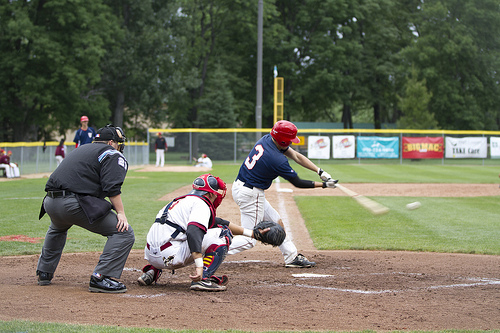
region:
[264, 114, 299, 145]
red helmet on player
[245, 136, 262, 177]
3 on back of the jersey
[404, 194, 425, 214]
baseball in the air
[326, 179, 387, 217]
bat in the hitter's hand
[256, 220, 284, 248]
black glove on catcher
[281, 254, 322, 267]
black shoe on right foot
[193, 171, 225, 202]
catcher's mask on face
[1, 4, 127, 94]
trees behind the fence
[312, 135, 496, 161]
advertisements on the fence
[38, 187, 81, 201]
belt on the umpire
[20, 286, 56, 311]
Small indentons in the dirt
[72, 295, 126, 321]
Small indentons in the dirt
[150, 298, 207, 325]
Small indentons in the dirt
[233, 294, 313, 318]
Small indentons in the dirt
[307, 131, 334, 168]
Banner hanging on fence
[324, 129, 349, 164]
Banner hanging on fence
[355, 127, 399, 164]
Banner hanging on fence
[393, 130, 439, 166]
Banner hanging on fence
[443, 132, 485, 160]
Banner hanging on fence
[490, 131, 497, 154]
Banner hanging on fence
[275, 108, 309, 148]
Person wearing red helmet.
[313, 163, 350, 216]
Person wearing white gloves.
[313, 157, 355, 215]
Person swinging baseball bat.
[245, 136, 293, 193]
Person wearing blue shirt.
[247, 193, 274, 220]
Person wearing white pants.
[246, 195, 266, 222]
Red stripe down pant leg.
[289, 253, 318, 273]
Person wearing black tennis shoes.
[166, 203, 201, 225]
Person wearing white shirt.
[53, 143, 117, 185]
Man wearing black shirt.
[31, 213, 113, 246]
Man wearing gray pants.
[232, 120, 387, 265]
A man wearing a blue jersey swinging a baseball bat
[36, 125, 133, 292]
An umpire in all black clothing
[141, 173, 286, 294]
A catcher squatting down and holding a catchers mitt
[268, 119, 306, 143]
Hard red baseball helmet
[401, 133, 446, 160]
Large red poster hanging on a fence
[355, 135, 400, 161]
Blue poster hanging on a fence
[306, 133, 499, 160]
A line of posters hanging on a chainlink fence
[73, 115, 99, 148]
Baseball player in a blue jersey standing in a field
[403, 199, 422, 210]
a white blurry looking baseball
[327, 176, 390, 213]
A wood baseball bat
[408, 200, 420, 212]
a white baseball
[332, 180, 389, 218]
a long brown baseball bat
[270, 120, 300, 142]
a red helmet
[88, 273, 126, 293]
a man's black shoe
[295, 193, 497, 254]
a section of green grass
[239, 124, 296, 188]
a man's blue jersey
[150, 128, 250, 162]
part of a gray chain link fence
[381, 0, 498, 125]
a large green tree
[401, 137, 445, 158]
a large red and yellow banner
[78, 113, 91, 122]
a red baseball cap